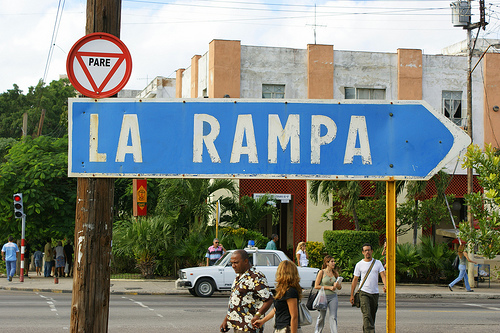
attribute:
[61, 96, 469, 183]
sign — blue, pointing, white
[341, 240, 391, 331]
person — walking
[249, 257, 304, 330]
woman — looking behind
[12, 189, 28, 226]
stoplight — red, traffic light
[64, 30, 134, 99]
sign — red colored, round, white, red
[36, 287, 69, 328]
line — faded, white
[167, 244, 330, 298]
car — white, small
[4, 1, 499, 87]
sky — white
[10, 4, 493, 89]
cloud — white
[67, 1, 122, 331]
pole — brown in color, wood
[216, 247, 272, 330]
man — walking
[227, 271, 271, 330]
shirt — floral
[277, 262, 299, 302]
hair — red